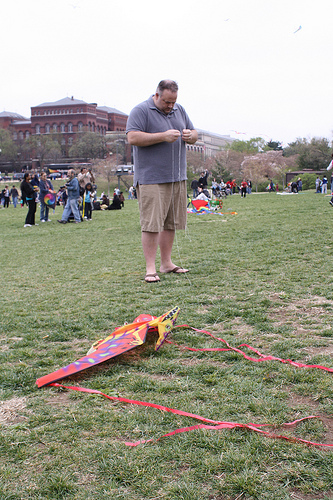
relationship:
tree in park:
[239, 147, 295, 186] [1, 169, 330, 497]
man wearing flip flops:
[126, 78, 197, 281] [164, 265, 186, 269]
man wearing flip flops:
[126, 78, 197, 281] [145, 270, 158, 280]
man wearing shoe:
[126, 78, 197, 281] [161, 263, 189, 275]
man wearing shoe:
[126, 78, 197, 281] [143, 271, 161, 284]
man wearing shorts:
[126, 78, 197, 281] [133, 179, 188, 233]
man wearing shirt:
[122, 73, 254, 288] [115, 106, 198, 156]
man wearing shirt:
[126, 78, 197, 281] [126, 97, 197, 189]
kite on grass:
[37, 306, 182, 388] [8, 179, 330, 495]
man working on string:
[126, 78, 197, 281] [170, 127, 194, 290]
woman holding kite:
[35, 166, 58, 234] [41, 187, 59, 209]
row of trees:
[4, 131, 132, 157] [0, 130, 127, 164]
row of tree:
[4, 131, 132, 157] [2, 127, 29, 163]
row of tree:
[4, 131, 132, 157] [19, 127, 62, 167]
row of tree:
[4, 131, 132, 157] [68, 127, 109, 156]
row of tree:
[4, 131, 132, 157] [107, 135, 127, 155]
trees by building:
[0, 130, 127, 164] [0, 98, 125, 142]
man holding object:
[193, 169, 213, 192] [203, 167, 211, 179]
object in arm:
[203, 167, 211, 179] [200, 171, 209, 178]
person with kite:
[237, 178, 246, 198] [240, 13, 306, 178]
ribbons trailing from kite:
[160, 136, 196, 194] [254, 11, 316, 84]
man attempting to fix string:
[126, 78, 197, 281] [170, 132, 224, 327]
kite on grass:
[37, 306, 182, 388] [0, 177, 331, 494]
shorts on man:
[125, 183, 190, 228] [126, 78, 197, 281]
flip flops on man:
[145, 263, 187, 281] [126, 78, 197, 281]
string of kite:
[169, 131, 219, 328] [37, 306, 182, 388]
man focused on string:
[126, 78, 197, 281] [169, 131, 219, 328]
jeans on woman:
[35, 170, 57, 223] [39, 177, 49, 219]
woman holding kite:
[39, 177, 49, 219] [41, 187, 59, 209]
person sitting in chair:
[189, 182, 212, 212] [202, 187, 214, 202]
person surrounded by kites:
[189, 182, 212, 212] [187, 199, 237, 215]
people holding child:
[22, 177, 33, 225] [29, 170, 39, 196]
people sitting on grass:
[88, 189, 124, 210] [8, 179, 330, 495]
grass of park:
[0, 177, 331, 494] [1, 169, 330, 497]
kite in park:
[37, 306, 182, 388] [1, 169, 330, 497]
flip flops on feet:
[142, 265, 186, 281] [130, 260, 197, 287]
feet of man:
[130, 260, 197, 287] [126, 78, 197, 281]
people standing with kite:
[16, 160, 99, 239] [41, 187, 59, 209]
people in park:
[16, 160, 99, 239] [1, 169, 330, 497]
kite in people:
[41, 187, 59, 209] [16, 160, 99, 239]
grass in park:
[0, 177, 331, 494] [1, 169, 330, 497]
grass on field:
[0, 177, 331, 494] [0, 174, 333, 497]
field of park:
[0, 174, 333, 497] [1, 169, 330, 497]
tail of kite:
[102, 384, 309, 466] [37, 306, 182, 388]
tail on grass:
[102, 384, 309, 466] [0, 177, 331, 494]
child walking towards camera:
[83, 183, 97, 219] [34, 225, 119, 300]